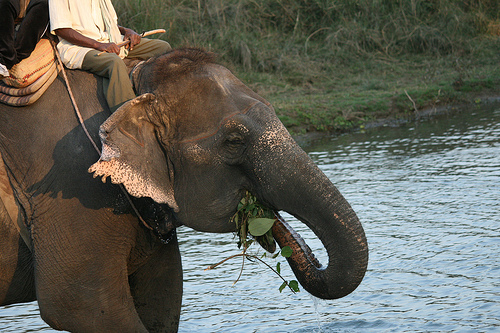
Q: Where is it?
A: This is at the shore.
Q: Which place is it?
A: It is a shore.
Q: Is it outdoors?
A: Yes, it is outdoors.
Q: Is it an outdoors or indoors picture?
A: It is outdoors.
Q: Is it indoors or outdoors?
A: It is outdoors.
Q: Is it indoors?
A: No, it is outdoors.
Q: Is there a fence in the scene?
A: No, there are no fences.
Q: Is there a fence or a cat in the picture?
A: No, there are no fences or cats.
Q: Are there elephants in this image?
A: Yes, there is an elephant.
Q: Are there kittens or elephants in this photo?
A: Yes, there is an elephant.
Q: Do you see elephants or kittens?
A: Yes, there is an elephant.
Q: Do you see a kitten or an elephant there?
A: Yes, there is an elephant.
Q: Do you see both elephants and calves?
A: No, there is an elephant but no calves.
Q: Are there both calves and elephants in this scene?
A: No, there is an elephant but no calves.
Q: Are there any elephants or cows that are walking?
A: Yes, the elephant is walking.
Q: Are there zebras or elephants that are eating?
A: Yes, the elephant is eating.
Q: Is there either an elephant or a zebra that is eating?
A: Yes, the elephant is eating.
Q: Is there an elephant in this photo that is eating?
A: Yes, there is an elephant that is eating.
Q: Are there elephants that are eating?
A: Yes, there is an elephant that is eating.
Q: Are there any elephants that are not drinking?
A: Yes, there is an elephant that is eating.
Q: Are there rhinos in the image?
A: No, there are no rhinos.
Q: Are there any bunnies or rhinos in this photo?
A: No, there are no rhinos or bunnies.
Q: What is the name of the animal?
A: The animal is an elephant.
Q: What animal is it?
A: The animal is an elephant.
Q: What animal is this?
A: This is an elephant.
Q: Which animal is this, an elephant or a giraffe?
A: This is an elephant.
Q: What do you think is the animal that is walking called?
A: The animal is an elephant.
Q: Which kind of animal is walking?
A: The animal is an elephant.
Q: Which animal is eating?
A: The animal is an elephant.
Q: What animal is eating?
A: The animal is an elephant.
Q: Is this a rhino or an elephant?
A: This is an elephant.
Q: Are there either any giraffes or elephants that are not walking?
A: No, there is an elephant but it is walking.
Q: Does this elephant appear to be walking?
A: Yes, the elephant is walking.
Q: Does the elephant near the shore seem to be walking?
A: Yes, the elephant is walking.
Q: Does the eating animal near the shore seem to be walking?
A: Yes, the elephant is walking.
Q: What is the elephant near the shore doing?
A: The elephant is walking.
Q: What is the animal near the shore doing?
A: The elephant is walking.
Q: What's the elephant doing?
A: The elephant is walking.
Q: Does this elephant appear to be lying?
A: No, the elephant is walking.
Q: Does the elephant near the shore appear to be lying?
A: No, the elephant is walking.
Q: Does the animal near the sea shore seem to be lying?
A: No, the elephant is walking.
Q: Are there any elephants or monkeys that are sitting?
A: No, there is an elephant but it is walking.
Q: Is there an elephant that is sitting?
A: No, there is an elephant but it is walking.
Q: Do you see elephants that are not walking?
A: No, there is an elephant but it is walking.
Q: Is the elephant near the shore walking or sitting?
A: The elephant is walking.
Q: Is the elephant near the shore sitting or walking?
A: The elephant is walking.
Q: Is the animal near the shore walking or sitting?
A: The elephant is walking.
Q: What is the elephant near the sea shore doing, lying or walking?
A: The elephant is walking.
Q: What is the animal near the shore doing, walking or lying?
A: The elephant is walking.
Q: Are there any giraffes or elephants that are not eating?
A: No, there is an elephant but it is eating.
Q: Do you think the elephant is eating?
A: Yes, the elephant is eating.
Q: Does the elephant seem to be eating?
A: Yes, the elephant is eating.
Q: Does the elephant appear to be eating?
A: Yes, the elephant is eating.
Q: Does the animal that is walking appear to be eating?
A: Yes, the elephant is eating.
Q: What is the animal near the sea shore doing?
A: The elephant is eating.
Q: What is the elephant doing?
A: The elephant is eating.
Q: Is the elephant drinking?
A: No, the elephant is eating.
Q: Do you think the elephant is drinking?
A: No, the elephant is eating.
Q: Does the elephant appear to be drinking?
A: No, the elephant is eating.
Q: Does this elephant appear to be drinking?
A: No, the elephant is eating.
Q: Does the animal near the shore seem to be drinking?
A: No, the elephant is eating.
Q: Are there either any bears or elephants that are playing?
A: No, there is an elephant but it is eating.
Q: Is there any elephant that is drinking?
A: No, there is an elephant but it is eating.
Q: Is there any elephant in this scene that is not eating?
A: No, there is an elephant but it is eating.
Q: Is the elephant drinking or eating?
A: The elephant is eating.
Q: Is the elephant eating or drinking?
A: The elephant is eating.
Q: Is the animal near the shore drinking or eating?
A: The elephant is eating.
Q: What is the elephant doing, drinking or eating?
A: The elephant is eating.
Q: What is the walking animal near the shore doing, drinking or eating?
A: The elephant is eating.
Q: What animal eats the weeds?
A: The elephant eats the weeds.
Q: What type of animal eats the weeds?
A: The animal is an elephant.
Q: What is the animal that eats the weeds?
A: The animal is an elephant.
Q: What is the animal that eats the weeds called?
A: The animal is an elephant.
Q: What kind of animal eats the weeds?
A: The animal is an elephant.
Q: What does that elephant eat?
A: The elephant eats weeds.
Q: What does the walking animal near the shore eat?
A: The elephant eats weeds.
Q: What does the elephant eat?
A: The elephant eats weeds.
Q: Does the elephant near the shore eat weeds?
A: Yes, the elephant eats weeds.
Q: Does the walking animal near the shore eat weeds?
A: Yes, the elephant eats weeds.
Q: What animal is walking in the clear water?
A: The elephant is walking in the water.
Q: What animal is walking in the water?
A: The elephant is walking in the water.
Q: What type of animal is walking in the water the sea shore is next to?
A: The animal is an elephant.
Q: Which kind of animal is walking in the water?
A: The animal is an elephant.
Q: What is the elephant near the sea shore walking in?
A: The elephant is walking in the water.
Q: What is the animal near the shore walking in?
A: The elephant is walking in the water.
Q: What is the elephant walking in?
A: The elephant is walking in the water.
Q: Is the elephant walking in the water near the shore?
A: Yes, the elephant is walking in the water.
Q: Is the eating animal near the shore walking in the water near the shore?
A: Yes, the elephant is walking in the water.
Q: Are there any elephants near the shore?
A: Yes, there is an elephant near the shore.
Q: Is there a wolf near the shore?
A: No, there is an elephant near the shore.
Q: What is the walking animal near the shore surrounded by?
A: The elephant is surrounded by the water.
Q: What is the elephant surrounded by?
A: The elephant is surrounded by the water.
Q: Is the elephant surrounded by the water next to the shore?
A: Yes, the elephant is surrounded by the water.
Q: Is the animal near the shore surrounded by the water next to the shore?
A: Yes, the elephant is surrounded by the water.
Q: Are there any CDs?
A: No, there are no cds.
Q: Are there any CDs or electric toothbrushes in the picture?
A: No, there are no CDs or electric toothbrushes.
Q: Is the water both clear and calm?
A: Yes, the water is clear and calm.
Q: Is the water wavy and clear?
A: No, the water is clear but calm.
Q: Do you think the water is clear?
A: Yes, the water is clear.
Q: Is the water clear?
A: Yes, the water is clear.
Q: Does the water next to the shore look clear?
A: Yes, the water is clear.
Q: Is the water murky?
A: No, the water is clear.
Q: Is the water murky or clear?
A: The water is clear.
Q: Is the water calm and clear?
A: Yes, the water is calm and clear.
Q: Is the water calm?
A: Yes, the water is calm.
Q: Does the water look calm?
A: Yes, the water is calm.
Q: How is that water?
A: The water is calm.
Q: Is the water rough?
A: No, the water is calm.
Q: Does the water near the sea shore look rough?
A: No, the water is calm.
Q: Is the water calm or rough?
A: The water is calm.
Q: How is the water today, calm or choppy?
A: The water is calm.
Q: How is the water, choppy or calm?
A: The water is calm.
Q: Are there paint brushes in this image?
A: No, there are no paint brushes.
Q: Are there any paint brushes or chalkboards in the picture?
A: No, there are no paint brushes or chalkboards.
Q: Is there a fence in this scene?
A: No, there are no fences.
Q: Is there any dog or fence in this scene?
A: No, there are no fences or dogs.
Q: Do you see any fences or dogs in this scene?
A: No, there are no fences or dogs.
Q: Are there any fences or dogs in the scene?
A: No, there are no fences or dogs.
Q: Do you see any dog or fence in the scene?
A: No, there are no fences or dogs.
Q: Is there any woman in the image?
A: No, there are no women.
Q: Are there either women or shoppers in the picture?
A: No, there are no women or shoppers.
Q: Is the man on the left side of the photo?
A: Yes, the man is on the left of the image.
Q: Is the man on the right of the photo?
A: No, the man is on the left of the image.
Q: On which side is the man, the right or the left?
A: The man is on the left of the image.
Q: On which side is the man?
A: The man is on the left of the image.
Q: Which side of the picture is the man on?
A: The man is on the left of the image.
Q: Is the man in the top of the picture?
A: Yes, the man is in the top of the image.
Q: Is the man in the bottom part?
A: No, the man is in the top of the image.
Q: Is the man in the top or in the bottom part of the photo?
A: The man is in the top of the image.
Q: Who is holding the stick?
A: The man is holding the stick.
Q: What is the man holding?
A: The man is holding the stick.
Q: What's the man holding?
A: The man is holding the stick.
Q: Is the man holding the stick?
A: Yes, the man is holding the stick.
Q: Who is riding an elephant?
A: The man is riding an elephant.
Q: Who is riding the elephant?
A: The man is riding an elephant.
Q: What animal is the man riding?
A: The man is riding an elephant.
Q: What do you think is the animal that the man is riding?
A: The animal is an elephant.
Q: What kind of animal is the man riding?
A: The man is riding an elephant.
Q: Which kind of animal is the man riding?
A: The man is riding an elephant.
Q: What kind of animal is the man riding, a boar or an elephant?
A: The man is riding an elephant.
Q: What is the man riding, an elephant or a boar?
A: The man is riding an elephant.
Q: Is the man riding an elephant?
A: Yes, the man is riding an elephant.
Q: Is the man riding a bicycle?
A: No, the man is riding an elephant.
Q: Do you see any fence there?
A: No, there are no fences.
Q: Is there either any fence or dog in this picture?
A: No, there are no fences or dogs.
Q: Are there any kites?
A: No, there are no kites.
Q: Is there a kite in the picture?
A: No, there are no kites.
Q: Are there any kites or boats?
A: No, there are no kites or boats.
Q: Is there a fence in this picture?
A: No, there are no fences.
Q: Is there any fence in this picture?
A: No, there are no fences.